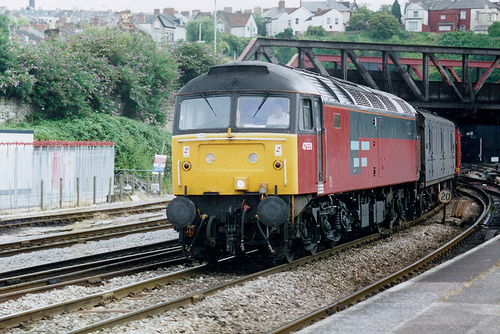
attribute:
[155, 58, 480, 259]
train — multi-colored, yellow, red, numbered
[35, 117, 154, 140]
bush — green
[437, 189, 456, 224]
sign — white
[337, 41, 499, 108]
bridge — metal, red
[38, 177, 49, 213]
post — wooden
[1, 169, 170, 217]
fence — metal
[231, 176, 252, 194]
light — white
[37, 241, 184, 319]
tracks — metal, rusted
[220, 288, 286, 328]
stones — piled, small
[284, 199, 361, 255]
wheels —  some, black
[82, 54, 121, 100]
flowers — purple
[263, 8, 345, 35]
house — white